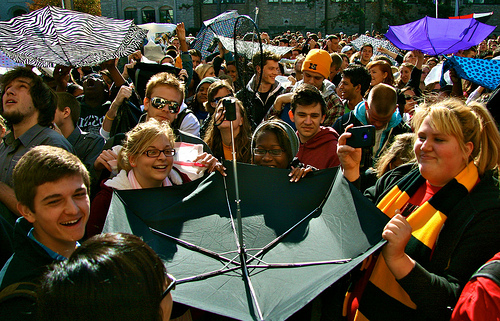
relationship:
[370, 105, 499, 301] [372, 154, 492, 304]
woman wearing a scarf